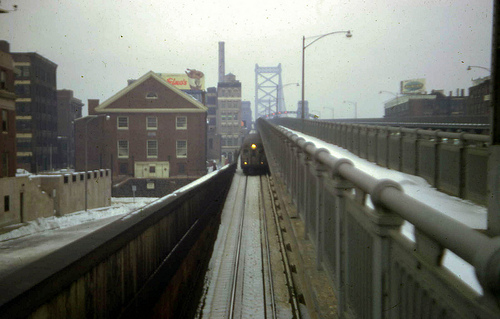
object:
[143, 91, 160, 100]
window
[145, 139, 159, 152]
glass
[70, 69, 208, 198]
building